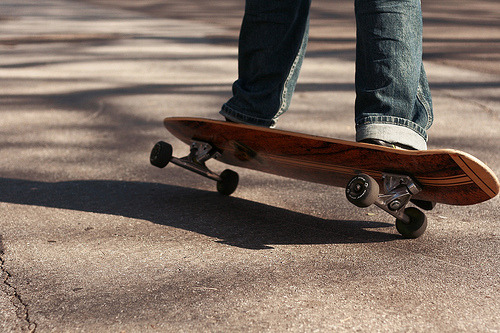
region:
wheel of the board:
[333, 163, 391, 210]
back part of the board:
[442, 144, 497, 202]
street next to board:
[117, 234, 217, 303]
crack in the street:
[0, 256, 65, 313]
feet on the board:
[211, 93, 434, 133]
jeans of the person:
[205, 9, 435, 87]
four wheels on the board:
[132, 143, 438, 251]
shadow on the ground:
[58, 51, 135, 107]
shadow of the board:
[134, 200, 253, 235]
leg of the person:
[201, 18, 325, 98]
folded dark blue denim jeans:
[366, 6, 430, 123]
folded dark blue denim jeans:
[347, 37, 434, 153]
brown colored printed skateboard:
[219, 117, 413, 208]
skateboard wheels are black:
[148, 133, 178, 171]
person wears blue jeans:
[230, 3, 465, 124]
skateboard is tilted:
[181, 103, 438, 222]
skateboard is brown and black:
[178, 114, 477, 206]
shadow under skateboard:
[6, 129, 341, 274]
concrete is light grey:
[71, 175, 217, 326]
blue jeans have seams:
[284, 16, 309, 112]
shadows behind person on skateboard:
[255, 0, 450, 100]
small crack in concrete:
[0, 253, 48, 323]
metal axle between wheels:
[167, 133, 237, 228]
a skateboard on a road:
[140, 102, 495, 238]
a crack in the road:
[1, 239, 51, 331]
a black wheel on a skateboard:
[342, 170, 373, 201]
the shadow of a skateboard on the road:
[5, 169, 392, 255]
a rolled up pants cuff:
[348, 110, 437, 148]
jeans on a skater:
[217, 0, 445, 144]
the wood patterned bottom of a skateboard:
[164, 110, 497, 209]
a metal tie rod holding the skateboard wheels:
[173, 140, 219, 184]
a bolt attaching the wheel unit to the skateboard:
[388, 195, 405, 212]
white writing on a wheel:
[345, 174, 371, 200]